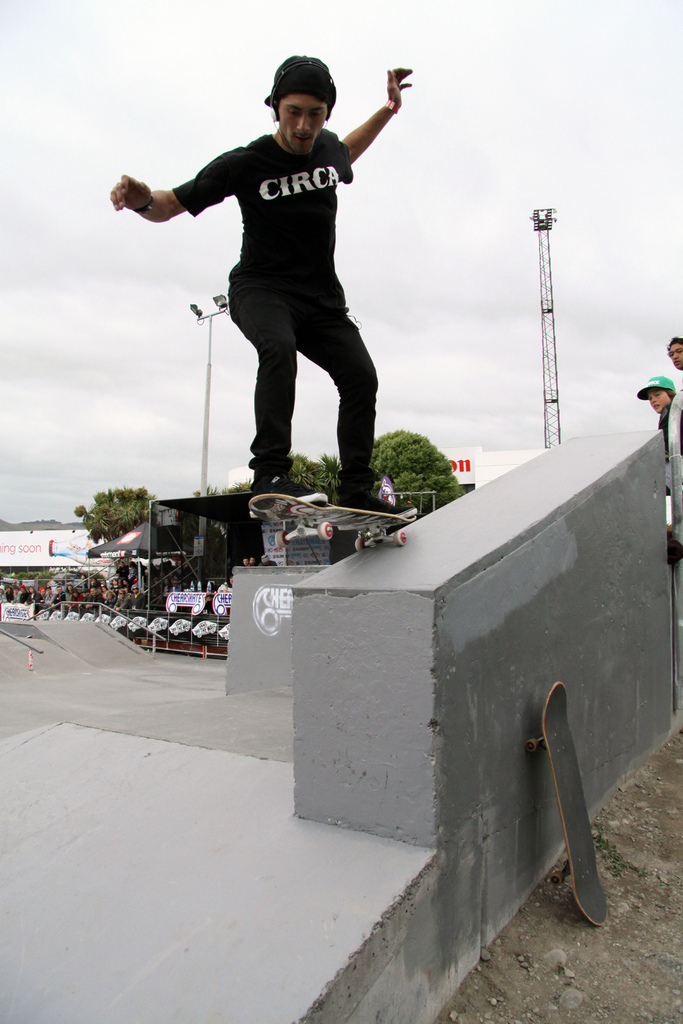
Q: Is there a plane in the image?
A: No, there are no airplanes.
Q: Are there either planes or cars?
A: No, there are no planes or cars.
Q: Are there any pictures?
A: No, there are no pictures.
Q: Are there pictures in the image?
A: No, there are no pictures.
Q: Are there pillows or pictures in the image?
A: No, there are no pictures or pillows.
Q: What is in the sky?
A: The clouds are in the sky.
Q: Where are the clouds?
A: The clouds are in the sky.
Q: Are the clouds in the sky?
A: Yes, the clouds are in the sky.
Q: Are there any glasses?
A: No, there are no glasses.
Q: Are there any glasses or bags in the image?
A: No, there are no glasses or bags.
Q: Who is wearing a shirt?
A: The guy is wearing a shirt.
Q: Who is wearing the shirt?
A: The guy is wearing a shirt.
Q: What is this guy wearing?
A: The guy is wearing a shirt.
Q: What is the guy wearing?
A: The guy is wearing a shirt.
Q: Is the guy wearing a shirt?
A: Yes, the guy is wearing a shirt.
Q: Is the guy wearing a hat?
A: No, the guy is wearing a shirt.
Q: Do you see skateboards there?
A: Yes, there is a skateboard.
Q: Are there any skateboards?
A: Yes, there is a skateboard.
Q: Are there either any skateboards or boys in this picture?
A: Yes, there is a skateboard.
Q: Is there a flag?
A: No, there are no flags.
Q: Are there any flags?
A: No, there are no flags.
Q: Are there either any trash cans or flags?
A: No, there are no flags or trash cans.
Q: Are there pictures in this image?
A: No, there are no pictures.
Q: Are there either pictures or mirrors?
A: No, there are no pictures or mirrors.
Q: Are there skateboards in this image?
A: Yes, there is a skateboard.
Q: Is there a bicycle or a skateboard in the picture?
A: Yes, there is a skateboard.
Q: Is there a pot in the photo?
A: No, there are no pots.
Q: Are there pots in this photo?
A: No, there are no pots.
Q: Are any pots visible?
A: No, there are no pots.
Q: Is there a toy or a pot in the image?
A: No, there are no pots or toys.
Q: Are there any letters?
A: Yes, there are letters.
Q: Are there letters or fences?
A: Yes, there are letters.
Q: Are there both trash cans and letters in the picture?
A: No, there are letters but no trash cans.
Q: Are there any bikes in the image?
A: No, there are no bikes.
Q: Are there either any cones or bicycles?
A: No, there are no bicycles or cones.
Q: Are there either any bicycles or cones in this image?
A: No, there are no bicycles or cones.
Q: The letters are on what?
A: The letters are on the wall.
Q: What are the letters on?
A: The letters are on the wall.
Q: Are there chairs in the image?
A: No, there are no chairs.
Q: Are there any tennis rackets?
A: No, there are no tennis rackets.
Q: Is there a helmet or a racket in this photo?
A: No, there are no rackets or helmets.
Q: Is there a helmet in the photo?
A: No, there are no helmets.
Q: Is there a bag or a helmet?
A: No, there are no helmets or bags.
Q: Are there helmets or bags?
A: No, there are no helmets or bags.